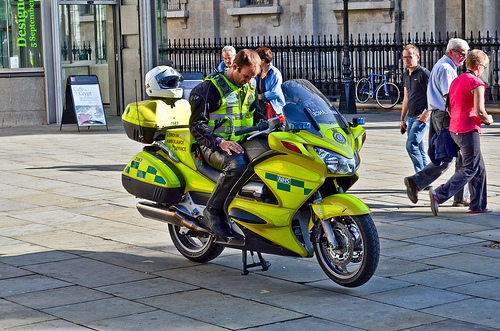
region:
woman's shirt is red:
[449, 71, 484, 137]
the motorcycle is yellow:
[115, 65, 396, 258]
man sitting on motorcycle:
[170, 41, 284, 232]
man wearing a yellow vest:
[186, 68, 266, 157]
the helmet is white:
[133, 54, 203, 126]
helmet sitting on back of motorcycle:
[119, 44, 199, 132]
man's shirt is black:
[395, 66, 432, 121]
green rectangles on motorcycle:
[122, 151, 339, 198]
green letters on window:
[6, 3, 43, 71]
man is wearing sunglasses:
[442, 36, 466, 58]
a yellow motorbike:
[90, 47, 413, 295]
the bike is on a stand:
[233, 245, 292, 285]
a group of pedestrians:
[376, 37, 493, 229]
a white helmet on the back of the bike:
[141, 61, 184, 108]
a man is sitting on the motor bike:
[181, 40, 286, 245]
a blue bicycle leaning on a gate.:
[355, 62, 403, 112]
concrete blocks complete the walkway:
[0, 180, 152, 330]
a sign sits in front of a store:
[50, 67, 110, 136]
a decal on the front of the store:
[7, 0, 52, 60]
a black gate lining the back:
[164, 29, 499, 106]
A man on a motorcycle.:
[116, 47, 393, 306]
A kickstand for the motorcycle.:
[236, 251, 272, 280]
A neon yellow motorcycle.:
[115, 89, 406, 291]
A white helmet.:
[137, 66, 190, 110]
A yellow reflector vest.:
[196, 70, 264, 168]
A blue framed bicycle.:
[356, 60, 406, 112]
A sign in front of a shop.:
[49, 68, 108, 130]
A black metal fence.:
[156, 28, 498, 105]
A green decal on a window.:
[9, 0, 44, 64]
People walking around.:
[376, 28, 498, 216]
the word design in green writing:
[8, 3, 35, 52]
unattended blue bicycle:
[353, 60, 401, 112]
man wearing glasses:
[394, 38, 424, 73]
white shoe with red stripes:
[424, 186, 449, 218]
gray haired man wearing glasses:
[439, 33, 472, 68]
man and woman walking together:
[398, 30, 495, 230]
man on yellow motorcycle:
[87, 33, 401, 303]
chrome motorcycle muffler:
[118, 187, 229, 242]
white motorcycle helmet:
[128, 56, 195, 104]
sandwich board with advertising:
[43, 66, 122, 138]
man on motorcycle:
[101, 40, 380, 288]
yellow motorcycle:
[126, 127, 388, 288]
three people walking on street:
[376, 30, 496, 221]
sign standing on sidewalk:
[55, 70, 110, 135]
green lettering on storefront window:
[5, 0, 36, 55]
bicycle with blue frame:
[353, 65, 398, 115]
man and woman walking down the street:
[425, 30, 495, 216]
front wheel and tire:
[311, 201, 376, 286]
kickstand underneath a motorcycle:
[229, 248, 275, 276]